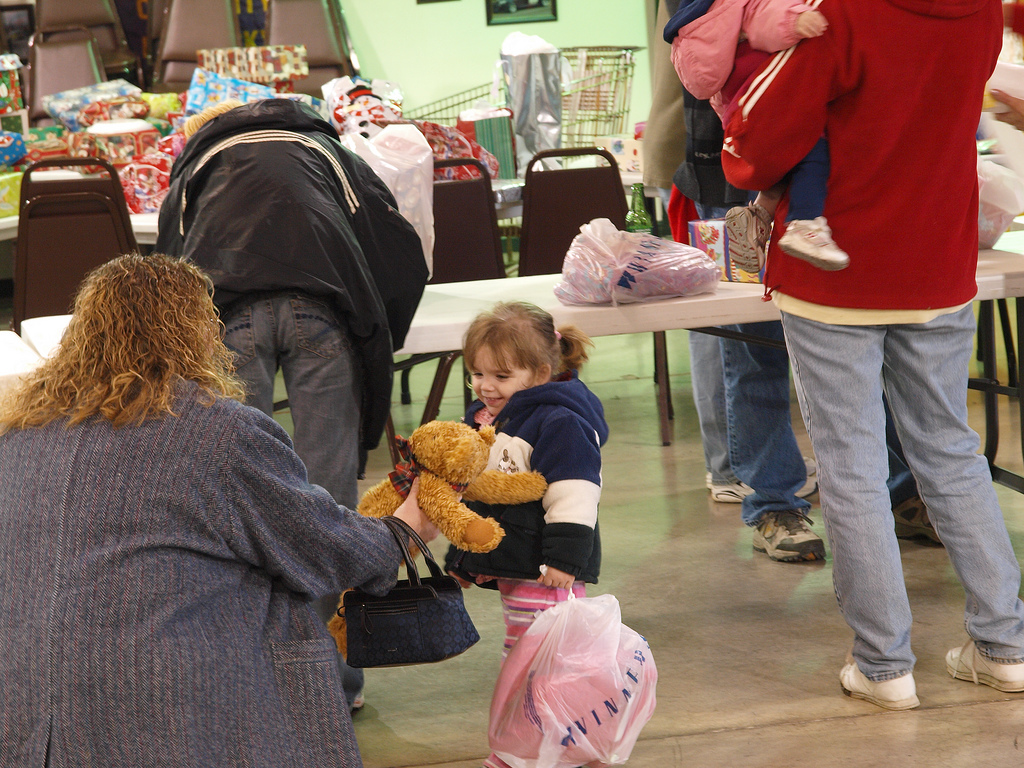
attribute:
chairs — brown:
[24, 4, 353, 84]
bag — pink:
[485, 580, 660, 766]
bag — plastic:
[549, 215, 716, 308]